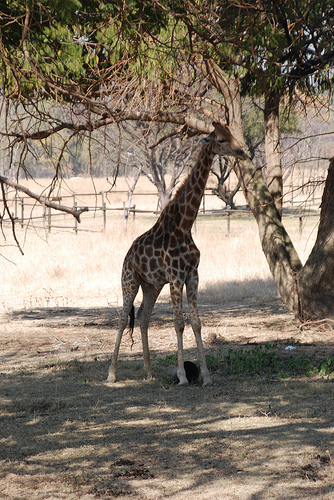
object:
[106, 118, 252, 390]
giraffe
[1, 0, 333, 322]
tree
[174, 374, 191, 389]
hoof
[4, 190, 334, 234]
fence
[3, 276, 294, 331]
shadow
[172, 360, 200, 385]
dish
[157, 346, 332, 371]
grass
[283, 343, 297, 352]
paper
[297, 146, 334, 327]
trunk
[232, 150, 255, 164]
mouth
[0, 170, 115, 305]
field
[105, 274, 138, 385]
leg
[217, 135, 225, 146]
eye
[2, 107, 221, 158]
branch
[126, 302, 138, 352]
tail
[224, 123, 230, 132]
horn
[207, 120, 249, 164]
head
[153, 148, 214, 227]
neck